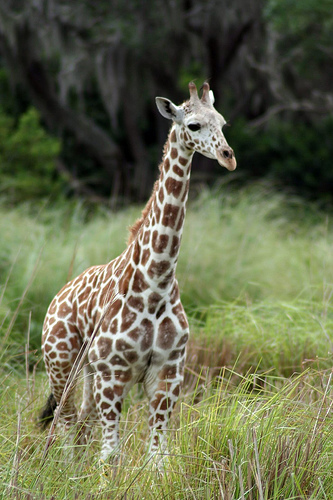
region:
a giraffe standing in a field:
[19, 84, 251, 480]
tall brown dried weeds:
[247, 418, 266, 493]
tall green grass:
[204, 395, 227, 443]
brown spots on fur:
[153, 314, 180, 354]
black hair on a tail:
[38, 392, 56, 431]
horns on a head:
[173, 83, 222, 106]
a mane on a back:
[144, 126, 161, 235]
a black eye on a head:
[183, 110, 212, 138]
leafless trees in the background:
[63, 77, 141, 162]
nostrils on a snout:
[214, 141, 249, 178]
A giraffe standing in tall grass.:
[28, 27, 265, 498]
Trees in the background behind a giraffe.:
[53, 3, 243, 204]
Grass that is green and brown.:
[192, 318, 289, 409]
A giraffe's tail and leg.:
[30, 313, 101, 437]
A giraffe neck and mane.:
[123, 102, 238, 245]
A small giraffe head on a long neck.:
[123, 75, 257, 251]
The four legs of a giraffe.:
[38, 314, 227, 486]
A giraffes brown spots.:
[86, 205, 223, 352]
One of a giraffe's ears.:
[150, 89, 185, 141]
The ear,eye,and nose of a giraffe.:
[148, 90, 248, 183]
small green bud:
[216, 455, 233, 468]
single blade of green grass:
[309, 472, 330, 497]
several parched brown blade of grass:
[7, 402, 66, 476]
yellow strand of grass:
[207, 369, 240, 427]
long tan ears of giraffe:
[153, 93, 189, 127]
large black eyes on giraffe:
[180, 117, 216, 138]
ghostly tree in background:
[33, 32, 156, 157]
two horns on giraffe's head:
[181, 82, 228, 106]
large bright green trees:
[12, 116, 62, 182]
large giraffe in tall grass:
[12, 81, 276, 431]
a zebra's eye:
[184, 118, 202, 132]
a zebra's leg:
[95, 371, 127, 487]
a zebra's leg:
[142, 380, 181, 460]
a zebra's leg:
[42, 365, 76, 452]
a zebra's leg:
[79, 370, 98, 456]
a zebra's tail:
[36, 391, 56, 426]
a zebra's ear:
[155, 92, 183, 119]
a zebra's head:
[154, 78, 239, 171]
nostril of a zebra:
[220, 147, 229, 157]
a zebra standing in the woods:
[40, 63, 291, 480]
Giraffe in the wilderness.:
[32, 81, 237, 493]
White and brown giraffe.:
[32, 82, 236, 493]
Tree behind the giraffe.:
[2, 1, 332, 213]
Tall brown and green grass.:
[192, 360, 331, 498]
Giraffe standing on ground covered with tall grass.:
[31, 80, 235, 477]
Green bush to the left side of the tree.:
[1, 108, 68, 219]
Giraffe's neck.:
[125, 152, 193, 275]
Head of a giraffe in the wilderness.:
[155, 80, 237, 180]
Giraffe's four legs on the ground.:
[51, 373, 184, 489]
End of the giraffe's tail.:
[36, 390, 57, 436]